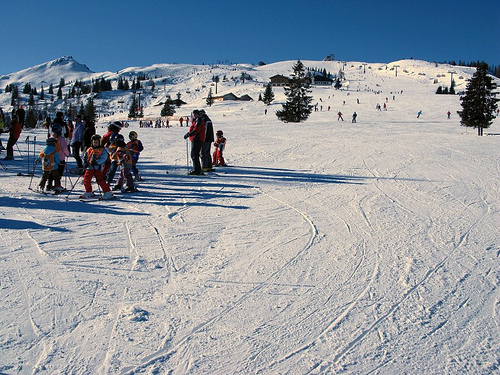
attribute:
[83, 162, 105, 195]
trousers — red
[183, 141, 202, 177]
pants — black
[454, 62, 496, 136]
leaves — green, a tree, pine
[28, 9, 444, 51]
sky — blue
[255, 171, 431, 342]
snow — white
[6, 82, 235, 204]
people — standing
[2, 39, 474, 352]
picture — daytime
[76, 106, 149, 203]
children — skating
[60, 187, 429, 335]
ground — white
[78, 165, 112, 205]
legs — apart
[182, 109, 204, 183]
man — a man